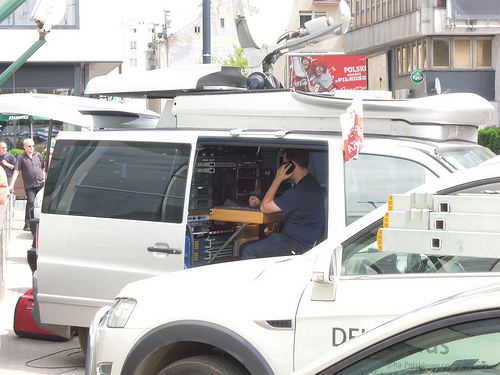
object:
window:
[342, 149, 427, 228]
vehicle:
[35, 85, 497, 365]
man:
[240, 148, 327, 260]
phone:
[282, 161, 296, 175]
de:
[328, 326, 366, 349]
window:
[430, 39, 455, 66]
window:
[410, 41, 420, 71]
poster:
[286, 52, 371, 94]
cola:
[292, 75, 309, 91]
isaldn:
[169, 68, 186, 70]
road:
[1, 199, 83, 371]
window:
[41, 139, 190, 224]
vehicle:
[84, 153, 500, 375]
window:
[450, 35, 475, 68]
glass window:
[413, 40, 424, 71]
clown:
[293, 56, 337, 94]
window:
[16, 59, 79, 92]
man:
[9, 137, 51, 230]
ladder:
[375, 191, 500, 260]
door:
[35, 129, 189, 328]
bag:
[12, 286, 80, 342]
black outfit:
[272, 173, 326, 247]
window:
[400, 45, 406, 76]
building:
[276, 0, 499, 102]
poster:
[336, 97, 361, 159]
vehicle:
[294, 286, 500, 374]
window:
[335, 317, 499, 373]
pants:
[240, 228, 311, 259]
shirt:
[272, 173, 329, 244]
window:
[395, 46, 401, 74]